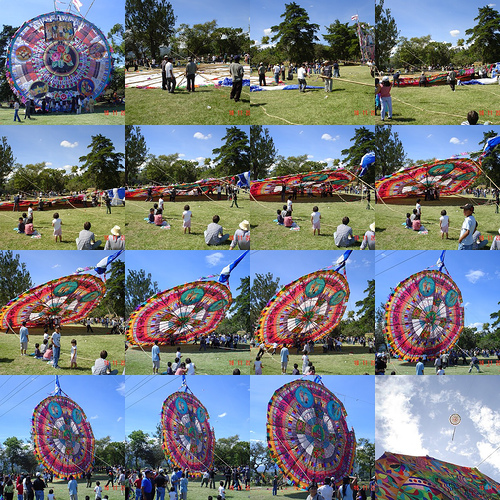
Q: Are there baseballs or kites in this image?
A: Yes, there is a kite.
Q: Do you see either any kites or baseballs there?
A: Yes, there is a kite.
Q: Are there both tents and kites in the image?
A: No, there is a kite but no tents.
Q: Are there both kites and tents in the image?
A: No, there is a kite but no tents.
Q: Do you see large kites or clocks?
A: Yes, there is a large kite.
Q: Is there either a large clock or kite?
A: Yes, there is a large kite.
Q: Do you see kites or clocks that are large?
A: Yes, the kite is large.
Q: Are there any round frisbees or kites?
A: Yes, there is a round kite.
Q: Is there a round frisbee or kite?
A: Yes, there is a round kite.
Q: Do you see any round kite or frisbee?
A: Yes, there is a round kite.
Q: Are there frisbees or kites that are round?
A: Yes, the kite is round.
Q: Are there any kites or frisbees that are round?
A: Yes, the kite is round.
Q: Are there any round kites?
A: Yes, there is a round kite.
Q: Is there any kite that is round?
A: Yes, there is a kite that is round.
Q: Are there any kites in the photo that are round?
A: Yes, there is a kite that is round.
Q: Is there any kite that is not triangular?
A: Yes, there is a round kite.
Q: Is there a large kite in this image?
A: Yes, there is a large kite.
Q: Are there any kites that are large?
A: Yes, there is a kite that is large.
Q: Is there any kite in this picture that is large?
A: Yes, there is a kite that is large.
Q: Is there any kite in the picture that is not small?
A: Yes, there is a large kite.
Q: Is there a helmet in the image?
A: No, there are no helmets.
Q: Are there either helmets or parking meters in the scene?
A: No, there are no helmets or parking meters.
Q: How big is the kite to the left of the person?
A: The kite is large.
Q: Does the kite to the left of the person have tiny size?
A: No, the kite is large.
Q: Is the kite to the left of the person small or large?
A: The kite is large.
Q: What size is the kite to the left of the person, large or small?
A: The kite is large.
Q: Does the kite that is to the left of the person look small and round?
A: No, the kite is round but large.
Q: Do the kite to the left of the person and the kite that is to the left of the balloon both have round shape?
A: Yes, both the kite and the kite are round.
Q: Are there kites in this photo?
A: Yes, there is a kite.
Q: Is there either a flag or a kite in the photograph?
A: Yes, there is a kite.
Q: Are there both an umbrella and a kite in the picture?
A: No, there is a kite but no umbrellas.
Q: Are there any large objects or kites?
A: Yes, there is a large kite.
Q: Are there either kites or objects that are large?
A: Yes, the kite is large.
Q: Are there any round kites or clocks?
A: Yes, there is a round kite.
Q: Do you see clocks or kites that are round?
A: Yes, the kite is round.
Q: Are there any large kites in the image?
A: Yes, there is a large kite.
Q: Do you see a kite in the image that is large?
A: Yes, there is a kite that is large.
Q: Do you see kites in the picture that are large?
A: Yes, there is a kite that is large.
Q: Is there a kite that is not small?
A: Yes, there is a large kite.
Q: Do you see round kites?
A: Yes, there is a round kite.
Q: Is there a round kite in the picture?
A: Yes, there is a round kite.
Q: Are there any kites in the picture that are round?
A: Yes, there is a kite that is round.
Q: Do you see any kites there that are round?
A: Yes, there is a kite that is round.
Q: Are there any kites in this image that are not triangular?
A: Yes, there is a round kite.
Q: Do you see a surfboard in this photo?
A: No, there are no surfboards.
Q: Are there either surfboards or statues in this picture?
A: No, there are no surfboards or statues.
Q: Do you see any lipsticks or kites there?
A: Yes, there is a kite.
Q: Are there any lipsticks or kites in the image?
A: Yes, there is a kite.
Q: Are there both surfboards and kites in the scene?
A: No, there is a kite but no surfboards.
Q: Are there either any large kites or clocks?
A: Yes, there is a large kite.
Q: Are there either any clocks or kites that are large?
A: Yes, the kite is large.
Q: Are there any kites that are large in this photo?
A: Yes, there is a large kite.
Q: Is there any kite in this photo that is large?
A: Yes, there is a kite that is large.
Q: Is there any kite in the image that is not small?
A: Yes, there is a large kite.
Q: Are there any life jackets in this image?
A: No, there are no life jackets.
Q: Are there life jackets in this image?
A: No, there are no life jackets.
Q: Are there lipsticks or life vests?
A: No, there are no life vests or lipsticks.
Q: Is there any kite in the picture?
A: Yes, there is a kite.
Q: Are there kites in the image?
A: Yes, there is a kite.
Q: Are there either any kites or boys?
A: Yes, there is a kite.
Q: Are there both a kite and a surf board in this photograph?
A: No, there is a kite but no surfboards.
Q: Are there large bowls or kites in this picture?
A: Yes, there is a large kite.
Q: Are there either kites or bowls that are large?
A: Yes, the kite is large.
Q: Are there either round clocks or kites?
A: Yes, there is a round kite.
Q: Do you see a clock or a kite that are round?
A: Yes, the kite is round.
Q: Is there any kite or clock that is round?
A: Yes, the kite is round.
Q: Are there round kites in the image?
A: Yes, there is a round kite.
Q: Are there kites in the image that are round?
A: Yes, there is a kite that is round.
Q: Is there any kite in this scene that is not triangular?
A: Yes, there is a round kite.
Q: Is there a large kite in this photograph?
A: Yes, there is a large kite.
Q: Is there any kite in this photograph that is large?
A: Yes, there is a kite that is large.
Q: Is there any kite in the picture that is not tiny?
A: Yes, there is a large kite.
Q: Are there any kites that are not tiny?
A: Yes, there is a large kite.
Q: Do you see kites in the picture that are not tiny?
A: Yes, there is a large kite.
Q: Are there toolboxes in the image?
A: No, there are no toolboxes.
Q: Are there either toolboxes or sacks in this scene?
A: No, there are no toolboxes or sacks.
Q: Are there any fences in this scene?
A: No, there are no fences.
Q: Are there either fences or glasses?
A: No, there are no fences or glasses.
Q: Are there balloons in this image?
A: Yes, there is a balloon.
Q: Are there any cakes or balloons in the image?
A: Yes, there is a balloon.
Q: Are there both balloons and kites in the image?
A: Yes, there are both a balloon and a kite.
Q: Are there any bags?
A: No, there are no bags.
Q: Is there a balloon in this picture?
A: Yes, there is a balloon.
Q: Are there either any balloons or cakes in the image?
A: Yes, there is a balloon.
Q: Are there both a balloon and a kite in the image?
A: Yes, there are both a balloon and a kite.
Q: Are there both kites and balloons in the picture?
A: Yes, there are both a balloon and a kite.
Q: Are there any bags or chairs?
A: No, there are no bags or chairs.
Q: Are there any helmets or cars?
A: No, there are no cars or helmets.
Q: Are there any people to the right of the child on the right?
A: Yes, there is a person to the right of the kid.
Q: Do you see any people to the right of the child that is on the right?
A: Yes, there is a person to the right of the kid.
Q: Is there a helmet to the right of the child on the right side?
A: No, there is a person to the right of the kid.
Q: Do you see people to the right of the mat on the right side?
A: Yes, there is a person to the right of the mat.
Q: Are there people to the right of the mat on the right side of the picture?
A: Yes, there is a person to the right of the mat.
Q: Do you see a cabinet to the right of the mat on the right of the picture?
A: No, there is a person to the right of the mat.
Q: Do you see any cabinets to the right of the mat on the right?
A: No, there is a person to the right of the mat.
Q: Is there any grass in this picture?
A: Yes, there is grass.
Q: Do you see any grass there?
A: Yes, there is grass.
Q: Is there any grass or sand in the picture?
A: Yes, there is grass.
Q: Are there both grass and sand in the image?
A: No, there is grass but no sand.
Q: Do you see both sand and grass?
A: No, there is grass but no sand.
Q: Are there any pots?
A: No, there are no pots.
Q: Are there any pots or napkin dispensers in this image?
A: No, there are no pots or napkin dispensers.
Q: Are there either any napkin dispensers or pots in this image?
A: No, there are no pots or napkin dispensers.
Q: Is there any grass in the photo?
A: Yes, there is grass.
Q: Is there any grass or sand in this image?
A: Yes, there is grass.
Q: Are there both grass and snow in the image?
A: No, there is grass but no snow.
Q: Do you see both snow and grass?
A: No, there is grass but no snow.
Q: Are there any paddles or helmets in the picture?
A: No, there are no helmets or paddles.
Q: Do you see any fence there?
A: No, there are no fences.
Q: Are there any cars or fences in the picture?
A: No, there are no fences or cars.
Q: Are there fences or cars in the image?
A: No, there are no fences or cars.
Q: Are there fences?
A: No, there are no fences.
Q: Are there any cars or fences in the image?
A: No, there are no fences or cars.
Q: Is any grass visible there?
A: Yes, there is grass.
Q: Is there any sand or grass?
A: Yes, there is grass.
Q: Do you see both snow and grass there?
A: No, there is grass but no snow.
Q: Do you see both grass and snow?
A: No, there is grass but no snow.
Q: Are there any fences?
A: No, there are no fences.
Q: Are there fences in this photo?
A: No, there are no fences.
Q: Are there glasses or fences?
A: No, there are no fences or glasses.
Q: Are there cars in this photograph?
A: No, there are no cars.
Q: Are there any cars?
A: No, there are no cars.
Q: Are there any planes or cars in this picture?
A: No, there are no cars or planes.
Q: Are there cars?
A: No, there are no cars.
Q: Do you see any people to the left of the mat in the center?
A: Yes, there is a person to the left of the mat.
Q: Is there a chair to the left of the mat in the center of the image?
A: No, there is a person to the left of the mat.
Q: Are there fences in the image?
A: No, there are no fences.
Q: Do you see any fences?
A: No, there are no fences.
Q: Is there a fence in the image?
A: No, there are no fences.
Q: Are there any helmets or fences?
A: No, there are no fences or helmets.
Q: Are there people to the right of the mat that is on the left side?
A: Yes, there is a person to the right of the mat.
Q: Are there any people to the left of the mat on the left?
A: No, the person is to the right of the mat.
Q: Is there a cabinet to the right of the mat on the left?
A: No, there is a person to the right of the mat.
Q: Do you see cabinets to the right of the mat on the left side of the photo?
A: No, there is a person to the right of the mat.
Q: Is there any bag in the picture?
A: No, there are no bags.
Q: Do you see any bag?
A: No, there are no bags.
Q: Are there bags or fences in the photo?
A: No, there are no bags or fences.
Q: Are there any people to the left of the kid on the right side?
A: Yes, there is a person to the left of the kid.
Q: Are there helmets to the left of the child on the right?
A: No, there is a person to the left of the kid.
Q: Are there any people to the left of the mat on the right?
A: Yes, there is a person to the left of the mat.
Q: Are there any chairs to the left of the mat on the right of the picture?
A: No, there is a person to the left of the mat.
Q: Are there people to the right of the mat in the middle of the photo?
A: Yes, there is a person to the right of the mat.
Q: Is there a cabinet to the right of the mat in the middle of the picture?
A: No, there is a person to the right of the mat.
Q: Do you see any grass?
A: Yes, there is grass.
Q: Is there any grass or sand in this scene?
A: Yes, there is grass.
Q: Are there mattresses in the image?
A: No, there are no mattresses.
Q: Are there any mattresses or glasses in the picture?
A: No, there are no mattresses or glasses.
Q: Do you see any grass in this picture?
A: Yes, there is grass.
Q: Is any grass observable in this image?
A: Yes, there is grass.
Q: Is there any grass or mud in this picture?
A: Yes, there is grass.